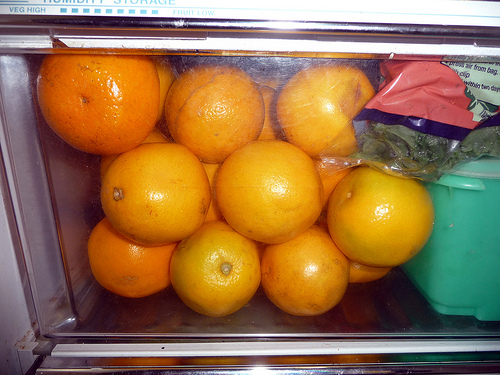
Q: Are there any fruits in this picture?
A: Yes, there is a fruit.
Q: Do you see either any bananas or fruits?
A: Yes, there is a fruit.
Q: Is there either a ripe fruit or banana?
A: Yes, there is a ripe fruit.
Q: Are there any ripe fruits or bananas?
A: Yes, there is a ripe fruit.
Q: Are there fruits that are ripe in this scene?
A: Yes, there is a ripe fruit.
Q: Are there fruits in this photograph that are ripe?
A: Yes, there is a fruit that is ripe.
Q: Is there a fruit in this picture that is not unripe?
A: Yes, there is an ripe fruit.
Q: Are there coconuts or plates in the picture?
A: No, there are no plates or coconuts.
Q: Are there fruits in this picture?
A: Yes, there is a fruit.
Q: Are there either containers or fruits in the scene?
A: Yes, there is a fruit.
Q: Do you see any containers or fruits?
A: Yes, there is a fruit.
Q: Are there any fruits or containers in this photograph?
A: Yes, there is a fruit.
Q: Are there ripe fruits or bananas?
A: Yes, there is a ripe fruit.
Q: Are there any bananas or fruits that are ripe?
A: Yes, the fruit is ripe.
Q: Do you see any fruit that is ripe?
A: Yes, there is a fruit that is ripe.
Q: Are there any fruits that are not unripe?
A: Yes, there is an ripe fruit.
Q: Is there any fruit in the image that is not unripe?
A: Yes, there is an ripe fruit.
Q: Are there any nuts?
A: No, there are no nuts.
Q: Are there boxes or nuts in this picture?
A: No, there are no nuts or boxes.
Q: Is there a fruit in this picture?
A: Yes, there is a fruit.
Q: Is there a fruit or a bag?
A: Yes, there is a fruit.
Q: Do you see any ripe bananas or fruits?
A: Yes, there is a ripe fruit.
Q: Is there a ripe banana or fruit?
A: Yes, there is a ripe fruit.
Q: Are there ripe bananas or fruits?
A: Yes, there is a ripe fruit.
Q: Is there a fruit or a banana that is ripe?
A: Yes, the fruit is ripe.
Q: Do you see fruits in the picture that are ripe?
A: Yes, there is a ripe fruit.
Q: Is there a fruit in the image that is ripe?
A: Yes, there is a fruit that is ripe.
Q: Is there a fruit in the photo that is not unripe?
A: Yes, there is an ripe fruit.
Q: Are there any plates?
A: No, there are no plates.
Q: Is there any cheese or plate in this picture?
A: No, there are no plates or cheese.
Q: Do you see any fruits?
A: Yes, there is a fruit.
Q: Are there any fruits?
A: Yes, there is a fruit.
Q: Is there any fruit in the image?
A: Yes, there is a fruit.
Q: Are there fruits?
A: Yes, there is a fruit.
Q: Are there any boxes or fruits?
A: Yes, there is a fruit.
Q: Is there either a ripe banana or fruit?
A: Yes, there is a ripe fruit.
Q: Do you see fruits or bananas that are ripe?
A: Yes, the fruit is ripe.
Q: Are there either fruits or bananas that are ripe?
A: Yes, the fruit is ripe.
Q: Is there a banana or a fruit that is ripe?
A: Yes, the fruit is ripe.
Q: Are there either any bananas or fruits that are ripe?
A: Yes, the fruit is ripe.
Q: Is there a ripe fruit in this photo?
A: Yes, there is a ripe fruit.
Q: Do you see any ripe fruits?
A: Yes, there is a ripe fruit.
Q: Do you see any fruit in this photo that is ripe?
A: Yes, there is a fruit that is ripe.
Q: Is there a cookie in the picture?
A: No, there are no cookies.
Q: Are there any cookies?
A: No, there are no cookies.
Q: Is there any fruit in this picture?
A: Yes, there is a fruit.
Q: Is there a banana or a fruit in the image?
A: Yes, there is a fruit.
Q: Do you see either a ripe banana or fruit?
A: Yes, there is a ripe fruit.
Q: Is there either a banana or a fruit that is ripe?
A: Yes, the fruit is ripe.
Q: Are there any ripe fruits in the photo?
A: Yes, there is a ripe fruit.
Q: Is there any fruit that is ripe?
A: Yes, there is a fruit that is ripe.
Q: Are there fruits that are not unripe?
A: Yes, there is an ripe fruit.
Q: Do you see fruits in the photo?
A: Yes, there is a fruit.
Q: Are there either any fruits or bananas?
A: Yes, there is a fruit.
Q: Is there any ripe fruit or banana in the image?
A: Yes, there is a ripe fruit.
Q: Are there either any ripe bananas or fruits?
A: Yes, there is a ripe fruit.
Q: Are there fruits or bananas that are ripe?
A: Yes, the fruit is ripe.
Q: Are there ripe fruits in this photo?
A: Yes, there is a ripe fruit.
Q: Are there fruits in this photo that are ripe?
A: Yes, there is a fruit that is ripe.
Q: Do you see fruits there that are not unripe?
A: Yes, there is an ripe fruit.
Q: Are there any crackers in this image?
A: No, there are no crackers.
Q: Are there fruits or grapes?
A: Yes, there is a fruit.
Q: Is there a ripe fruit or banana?
A: Yes, there is a ripe fruit.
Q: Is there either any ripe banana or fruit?
A: Yes, there is a ripe fruit.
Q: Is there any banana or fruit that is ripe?
A: Yes, the fruit is ripe.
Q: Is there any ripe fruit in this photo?
A: Yes, there is a ripe fruit.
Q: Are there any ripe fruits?
A: Yes, there is a ripe fruit.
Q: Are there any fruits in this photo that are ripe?
A: Yes, there is a fruit that is ripe.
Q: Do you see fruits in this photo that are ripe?
A: Yes, there is a fruit that is ripe.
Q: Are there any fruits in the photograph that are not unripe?
A: Yes, there is an ripe fruit.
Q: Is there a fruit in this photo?
A: Yes, there is a fruit.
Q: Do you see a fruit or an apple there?
A: Yes, there is a fruit.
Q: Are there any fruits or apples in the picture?
A: Yes, there is a fruit.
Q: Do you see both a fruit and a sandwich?
A: No, there is a fruit but no sandwiches.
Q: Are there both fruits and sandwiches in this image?
A: No, there is a fruit but no sandwiches.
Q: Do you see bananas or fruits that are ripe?
A: Yes, the fruit is ripe.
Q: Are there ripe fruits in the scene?
A: Yes, there is a ripe fruit.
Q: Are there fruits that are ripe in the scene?
A: Yes, there is a ripe fruit.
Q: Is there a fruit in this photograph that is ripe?
A: Yes, there is a fruit that is ripe.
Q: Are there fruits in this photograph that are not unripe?
A: Yes, there is an ripe fruit.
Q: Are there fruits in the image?
A: Yes, there is a fruit.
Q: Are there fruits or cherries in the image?
A: Yes, there is a fruit.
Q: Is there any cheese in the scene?
A: No, there is no cheese.